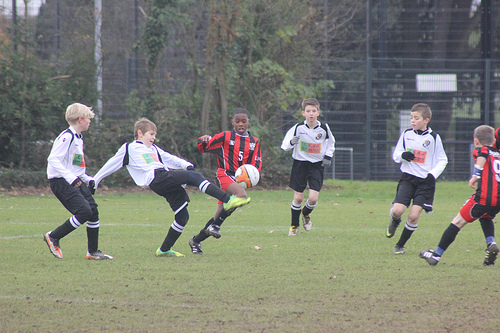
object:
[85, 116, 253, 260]
kid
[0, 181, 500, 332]
field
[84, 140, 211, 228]
uniform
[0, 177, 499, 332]
grass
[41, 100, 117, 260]
kid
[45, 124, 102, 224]
uniform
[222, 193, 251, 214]
shoe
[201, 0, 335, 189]
tree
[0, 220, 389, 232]
line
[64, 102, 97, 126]
hair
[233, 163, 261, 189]
soccer ball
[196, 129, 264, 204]
uniform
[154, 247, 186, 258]
shoe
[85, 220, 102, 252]
sock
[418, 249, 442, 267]
shoe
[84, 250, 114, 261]
shoe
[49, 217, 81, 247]
sock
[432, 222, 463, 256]
sock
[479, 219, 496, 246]
sock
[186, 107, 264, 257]
kid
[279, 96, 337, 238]
kid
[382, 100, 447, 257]
kid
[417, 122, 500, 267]
kid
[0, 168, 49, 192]
hedges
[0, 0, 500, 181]
fence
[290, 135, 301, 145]
glove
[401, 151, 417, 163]
glove